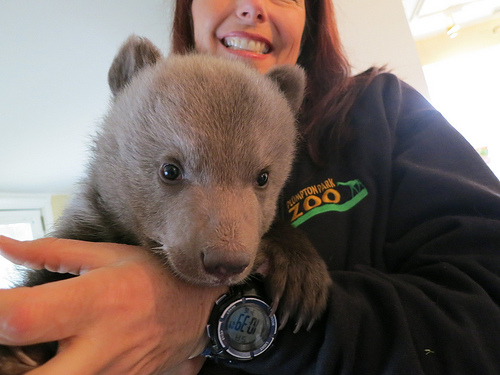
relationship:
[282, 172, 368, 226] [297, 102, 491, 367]
logo embroidered on shirt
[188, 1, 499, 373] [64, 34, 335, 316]
woman holding bear cub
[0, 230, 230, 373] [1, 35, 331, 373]
hand under bear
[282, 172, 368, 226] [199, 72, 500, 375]
logo on jacket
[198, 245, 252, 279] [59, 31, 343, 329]
nose on bear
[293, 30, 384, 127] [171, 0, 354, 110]
hair on head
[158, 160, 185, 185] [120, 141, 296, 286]
eye in face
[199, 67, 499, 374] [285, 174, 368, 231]
sweatshirt with logo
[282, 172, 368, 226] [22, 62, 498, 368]
logo on sweatshirt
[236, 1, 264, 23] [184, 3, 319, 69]
nose on woman's face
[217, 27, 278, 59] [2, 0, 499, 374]
smile on a face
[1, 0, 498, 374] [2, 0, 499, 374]
woman has a face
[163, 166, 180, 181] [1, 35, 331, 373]
eye of bear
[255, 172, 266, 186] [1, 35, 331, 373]
eye of bear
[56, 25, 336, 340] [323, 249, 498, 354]
bear cub in arm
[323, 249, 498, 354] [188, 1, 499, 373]
arm of woman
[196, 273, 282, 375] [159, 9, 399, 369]
watch on woman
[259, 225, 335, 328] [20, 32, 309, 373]
paw of bear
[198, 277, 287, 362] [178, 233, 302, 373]
watch on wrist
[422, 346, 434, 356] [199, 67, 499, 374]
lint on sweatshirt